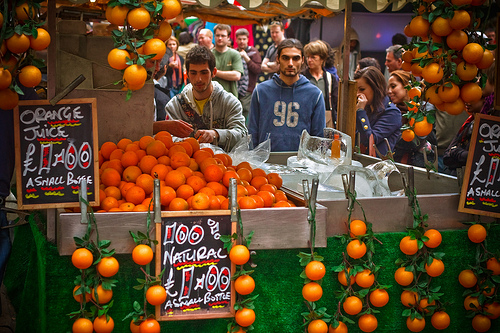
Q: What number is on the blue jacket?
A: 96.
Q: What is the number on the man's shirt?
A: 96.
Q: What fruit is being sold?
A: Oranges.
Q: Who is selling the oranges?
A: The young man on the left.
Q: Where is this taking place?
A: Outdoor market.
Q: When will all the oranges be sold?
A: No indication.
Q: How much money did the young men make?
A: No indication.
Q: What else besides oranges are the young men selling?
A: Orange juice.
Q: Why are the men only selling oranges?
A: Oranges are the only product the men have.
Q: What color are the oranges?
A: Orange.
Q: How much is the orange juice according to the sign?
A: 1 pound for a small bottle.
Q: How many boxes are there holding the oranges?
A: 1.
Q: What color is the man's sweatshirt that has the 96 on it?
A: Blue.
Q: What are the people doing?
A: Shopping for oranges.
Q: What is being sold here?
A: Orange Juice.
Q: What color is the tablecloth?
A: Green.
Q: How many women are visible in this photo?
A: 3.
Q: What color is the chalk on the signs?
A: White, yellow, and red.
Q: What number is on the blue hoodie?
A: 96.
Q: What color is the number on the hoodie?
A: White.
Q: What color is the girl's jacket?
A: Blue.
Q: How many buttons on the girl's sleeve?
A: 2.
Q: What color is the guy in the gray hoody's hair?
A: Brown.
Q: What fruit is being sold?
A: Oranges.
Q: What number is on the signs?
A: 100.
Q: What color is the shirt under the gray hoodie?
A: Yellow.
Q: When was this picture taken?
A: Daytime.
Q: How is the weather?
A: Clear.